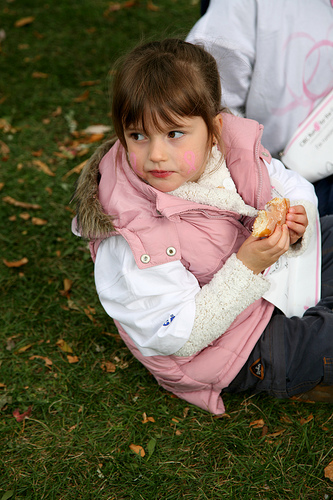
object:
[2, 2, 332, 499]
grass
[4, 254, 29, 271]
leaf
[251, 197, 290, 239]
donut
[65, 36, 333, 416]
girl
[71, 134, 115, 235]
fur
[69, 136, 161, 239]
hood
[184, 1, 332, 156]
shirt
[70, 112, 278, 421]
vest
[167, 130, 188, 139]
eye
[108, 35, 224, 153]
hair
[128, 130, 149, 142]
eye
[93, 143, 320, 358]
shirt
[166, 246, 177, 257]
button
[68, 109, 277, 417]
jacket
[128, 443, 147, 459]
leaf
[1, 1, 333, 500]
ground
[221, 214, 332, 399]
pants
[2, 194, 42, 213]
leaf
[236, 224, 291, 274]
hands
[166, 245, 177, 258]
metal stud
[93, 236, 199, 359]
sleeve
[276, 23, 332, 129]
symbol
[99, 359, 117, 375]
leaf